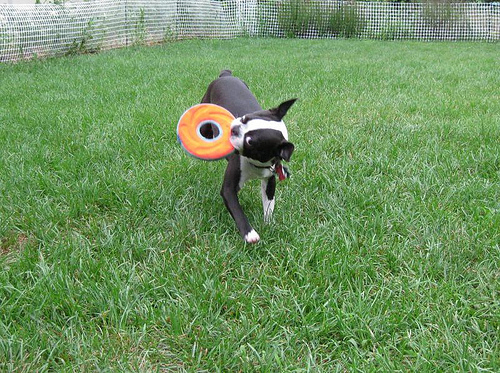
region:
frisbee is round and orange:
[175, 103, 236, 160]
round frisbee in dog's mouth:
[176, 104, 236, 158]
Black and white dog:
[199, 70, 302, 240]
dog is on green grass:
[1, 37, 497, 370]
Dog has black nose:
[230, 126, 240, 140]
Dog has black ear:
[273, 99, 296, 119]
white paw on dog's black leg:
[243, 227, 258, 246]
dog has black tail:
[217, 68, 231, 76]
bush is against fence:
[276, 3, 321, 39]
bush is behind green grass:
[329, 2, 364, 38]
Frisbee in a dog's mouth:
[169, 62, 305, 247]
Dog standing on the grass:
[1, 31, 496, 370]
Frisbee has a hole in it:
[172, 100, 241, 161]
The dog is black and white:
[194, 63, 304, 248]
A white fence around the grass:
[2, 3, 497, 62]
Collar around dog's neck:
[248, 157, 288, 183]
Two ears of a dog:
[273, 93, 300, 166]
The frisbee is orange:
[174, 98, 243, 163]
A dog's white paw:
[238, 223, 262, 246]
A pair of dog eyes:
[237, 109, 257, 151]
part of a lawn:
[396, 261, 411, 282]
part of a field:
[341, 265, 366, 295]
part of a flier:
[203, 136, 215, 153]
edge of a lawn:
[338, 233, 347, 253]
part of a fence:
[330, 35, 339, 48]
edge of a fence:
[56, 46, 65, 48]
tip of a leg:
[252, 231, 257, 235]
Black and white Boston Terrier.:
[168, 62, 308, 264]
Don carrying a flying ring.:
[161, 90, 308, 169]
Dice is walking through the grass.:
[172, 66, 299, 263]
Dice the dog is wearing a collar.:
[169, 102, 305, 178]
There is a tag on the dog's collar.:
[263, 158, 318, 182]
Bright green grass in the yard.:
[332, 58, 462, 238]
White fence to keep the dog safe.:
[8, 5, 170, 63]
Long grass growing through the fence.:
[254, 6, 359, 40]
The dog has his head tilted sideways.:
[162, 80, 325, 167]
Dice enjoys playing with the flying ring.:
[171, 83, 338, 179]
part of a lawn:
[423, 298, 438, 325]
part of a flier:
[174, 137, 180, 145]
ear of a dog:
[284, 145, 295, 160]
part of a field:
[371, 240, 388, 268]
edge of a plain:
[267, 275, 287, 303]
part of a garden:
[119, 264, 146, 290]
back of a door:
[233, 83, 240, 97]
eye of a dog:
[243, 129, 252, 152]